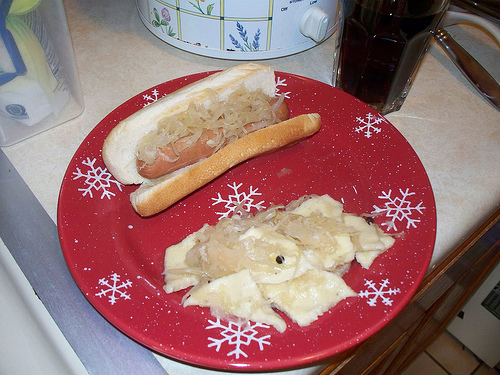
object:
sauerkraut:
[200, 91, 262, 132]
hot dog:
[97, 50, 325, 223]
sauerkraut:
[194, 217, 256, 271]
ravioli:
[180, 271, 286, 334]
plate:
[28, 58, 441, 368]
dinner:
[93, 59, 398, 336]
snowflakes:
[367, 185, 428, 231]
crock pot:
[139, 2, 343, 61]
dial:
[301, 7, 342, 46]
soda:
[342, 8, 418, 83]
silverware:
[425, 27, 500, 109]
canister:
[0, 0, 92, 149]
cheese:
[169, 111, 216, 132]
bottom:
[333, 0, 453, 116]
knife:
[436, 31, 500, 114]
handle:
[443, 9, 499, 56]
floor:
[416, 328, 482, 375]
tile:
[414, 325, 481, 375]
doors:
[378, 246, 500, 372]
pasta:
[189, 224, 280, 279]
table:
[0, 13, 499, 375]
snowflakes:
[95, 272, 133, 306]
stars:
[83, 165, 109, 191]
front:
[322, 212, 500, 375]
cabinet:
[314, 210, 498, 375]